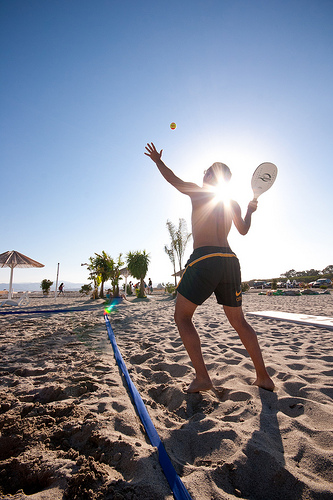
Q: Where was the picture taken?
A: It was taken at the beach.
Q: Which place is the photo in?
A: It is at the beach.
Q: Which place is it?
A: It is a beach.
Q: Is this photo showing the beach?
A: Yes, it is showing the beach.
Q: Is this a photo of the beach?
A: Yes, it is showing the beach.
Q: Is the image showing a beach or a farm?
A: It is showing a beach.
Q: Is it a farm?
A: No, it is a beach.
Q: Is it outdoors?
A: Yes, it is outdoors.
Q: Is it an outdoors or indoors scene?
A: It is outdoors.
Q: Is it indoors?
A: No, it is outdoors.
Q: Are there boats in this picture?
A: No, there are no boats.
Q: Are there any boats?
A: No, there are no boats.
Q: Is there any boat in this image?
A: No, there are no boats.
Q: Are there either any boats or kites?
A: No, there are no boats or kites.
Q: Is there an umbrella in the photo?
A: Yes, there is an umbrella.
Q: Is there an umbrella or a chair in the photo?
A: Yes, there is an umbrella.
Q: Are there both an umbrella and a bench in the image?
A: No, there is an umbrella but no benches.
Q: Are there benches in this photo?
A: No, there are no benches.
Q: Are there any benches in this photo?
A: No, there are no benches.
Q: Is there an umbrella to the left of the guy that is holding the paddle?
A: Yes, there is an umbrella to the left of the guy.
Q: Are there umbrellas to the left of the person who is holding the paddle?
A: Yes, there is an umbrella to the left of the guy.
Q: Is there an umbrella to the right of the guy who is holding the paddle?
A: No, the umbrella is to the left of the guy.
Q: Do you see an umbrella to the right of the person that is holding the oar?
A: No, the umbrella is to the left of the guy.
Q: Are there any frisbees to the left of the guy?
A: No, there is an umbrella to the left of the guy.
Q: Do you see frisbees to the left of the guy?
A: No, there is an umbrella to the left of the guy.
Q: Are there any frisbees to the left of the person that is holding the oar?
A: No, there is an umbrella to the left of the guy.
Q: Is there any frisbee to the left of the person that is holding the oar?
A: No, there is an umbrella to the left of the guy.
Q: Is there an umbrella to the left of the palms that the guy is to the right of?
A: Yes, there is an umbrella to the left of the palms.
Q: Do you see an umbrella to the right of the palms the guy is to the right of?
A: No, the umbrella is to the left of the palm trees.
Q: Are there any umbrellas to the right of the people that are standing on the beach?
A: Yes, there is an umbrella to the right of the people.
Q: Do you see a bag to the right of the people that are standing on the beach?
A: No, there is an umbrella to the right of the people.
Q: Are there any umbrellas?
A: Yes, there is an umbrella.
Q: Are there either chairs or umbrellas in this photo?
A: Yes, there is an umbrella.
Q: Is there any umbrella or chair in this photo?
A: Yes, there is an umbrella.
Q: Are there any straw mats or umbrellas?
A: Yes, there is a straw umbrella.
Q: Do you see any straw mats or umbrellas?
A: Yes, there is a straw umbrella.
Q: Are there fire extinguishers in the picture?
A: No, there are no fire extinguishers.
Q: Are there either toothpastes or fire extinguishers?
A: No, there are no fire extinguishers or toothpastes.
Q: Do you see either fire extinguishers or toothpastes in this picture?
A: No, there are no fire extinguishers or toothpastes.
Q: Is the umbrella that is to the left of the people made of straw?
A: Yes, the umbrella is made of straw.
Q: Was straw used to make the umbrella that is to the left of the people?
A: Yes, the umbrella is made of straw.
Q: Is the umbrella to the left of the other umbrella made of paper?
A: No, the umbrella is made of straw.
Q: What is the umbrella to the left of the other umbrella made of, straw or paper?
A: The umbrella is made of straw.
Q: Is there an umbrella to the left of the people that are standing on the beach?
A: Yes, there is an umbrella to the left of the people.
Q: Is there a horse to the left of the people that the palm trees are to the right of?
A: No, there is an umbrella to the left of the people.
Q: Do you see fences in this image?
A: No, there are no fences.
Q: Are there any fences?
A: No, there are no fences.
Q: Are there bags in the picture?
A: No, there are no bags.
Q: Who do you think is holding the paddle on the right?
A: The guy is holding the oar.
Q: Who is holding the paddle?
A: The guy is holding the oar.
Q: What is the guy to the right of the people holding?
A: The guy is holding the oar.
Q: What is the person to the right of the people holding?
A: The guy is holding the oar.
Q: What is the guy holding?
A: The guy is holding the oar.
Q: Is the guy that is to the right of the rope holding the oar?
A: Yes, the guy is holding the oar.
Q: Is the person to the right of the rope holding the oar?
A: Yes, the guy is holding the oar.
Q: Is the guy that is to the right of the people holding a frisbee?
A: No, the guy is holding the oar.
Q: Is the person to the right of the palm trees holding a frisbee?
A: No, the guy is holding the oar.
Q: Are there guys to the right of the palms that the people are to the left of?
A: Yes, there is a guy to the right of the palm trees.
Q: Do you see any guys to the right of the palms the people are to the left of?
A: Yes, there is a guy to the right of the palm trees.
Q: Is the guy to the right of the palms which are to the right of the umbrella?
A: Yes, the guy is to the right of the palm trees.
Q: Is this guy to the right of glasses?
A: No, the guy is to the right of the palm trees.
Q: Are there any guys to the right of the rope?
A: Yes, there is a guy to the right of the rope.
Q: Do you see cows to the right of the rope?
A: No, there is a guy to the right of the rope.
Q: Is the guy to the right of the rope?
A: Yes, the guy is to the right of the rope.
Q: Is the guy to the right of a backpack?
A: No, the guy is to the right of the rope.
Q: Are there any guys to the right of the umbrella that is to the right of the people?
A: Yes, there is a guy to the right of the umbrella.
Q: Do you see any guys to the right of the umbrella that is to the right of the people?
A: Yes, there is a guy to the right of the umbrella.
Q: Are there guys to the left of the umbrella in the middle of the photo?
A: No, the guy is to the right of the umbrella.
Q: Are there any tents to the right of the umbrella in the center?
A: No, there is a guy to the right of the umbrella.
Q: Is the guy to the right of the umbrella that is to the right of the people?
A: Yes, the guy is to the right of the umbrella.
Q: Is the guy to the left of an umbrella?
A: No, the guy is to the right of an umbrella.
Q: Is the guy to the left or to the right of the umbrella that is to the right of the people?
A: The guy is to the right of the umbrella.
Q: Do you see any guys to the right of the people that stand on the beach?
A: Yes, there is a guy to the right of the people.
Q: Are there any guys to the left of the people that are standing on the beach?
A: No, the guy is to the right of the people.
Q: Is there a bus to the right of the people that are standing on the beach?
A: No, there is a guy to the right of the people.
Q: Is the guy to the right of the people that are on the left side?
A: Yes, the guy is to the right of the people.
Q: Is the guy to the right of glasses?
A: No, the guy is to the right of the people.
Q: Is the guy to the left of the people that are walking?
A: No, the guy is to the right of the people.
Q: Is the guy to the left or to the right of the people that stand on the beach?
A: The guy is to the right of the people.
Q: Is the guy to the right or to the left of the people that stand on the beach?
A: The guy is to the right of the people.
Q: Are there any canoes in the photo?
A: No, there are no canoes.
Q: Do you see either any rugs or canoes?
A: No, there are no canoes or rugs.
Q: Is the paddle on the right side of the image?
A: Yes, the paddle is on the right of the image.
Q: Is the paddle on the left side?
A: No, the paddle is on the right of the image.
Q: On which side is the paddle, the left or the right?
A: The paddle is on the right of the image.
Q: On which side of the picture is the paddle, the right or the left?
A: The paddle is on the right of the image.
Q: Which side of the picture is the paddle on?
A: The paddle is on the right of the image.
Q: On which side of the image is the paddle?
A: The paddle is on the right of the image.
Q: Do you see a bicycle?
A: No, there are no bicycles.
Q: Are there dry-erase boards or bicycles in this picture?
A: No, there are no bicycles or dry-erase boards.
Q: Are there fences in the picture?
A: No, there are no fences.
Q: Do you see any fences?
A: No, there are no fences.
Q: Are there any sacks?
A: No, there are no sacks.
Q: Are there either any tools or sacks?
A: No, there are no sacks or tools.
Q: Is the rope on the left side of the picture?
A: Yes, the rope is on the left of the image.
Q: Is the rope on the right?
A: No, the rope is on the left of the image.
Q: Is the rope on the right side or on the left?
A: The rope is on the left of the image.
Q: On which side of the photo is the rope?
A: The rope is on the left of the image.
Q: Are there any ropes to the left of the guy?
A: Yes, there is a rope to the left of the guy.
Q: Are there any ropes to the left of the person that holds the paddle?
A: Yes, there is a rope to the left of the guy.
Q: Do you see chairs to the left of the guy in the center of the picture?
A: No, there is a rope to the left of the guy.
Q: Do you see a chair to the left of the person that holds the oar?
A: No, there is a rope to the left of the guy.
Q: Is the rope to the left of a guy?
A: Yes, the rope is to the left of a guy.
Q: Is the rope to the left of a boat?
A: No, the rope is to the left of a guy.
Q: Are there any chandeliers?
A: No, there are no chandeliers.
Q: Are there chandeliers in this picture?
A: No, there are no chandeliers.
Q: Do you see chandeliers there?
A: No, there are no chandeliers.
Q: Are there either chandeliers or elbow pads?
A: No, there are no chandeliers or elbow pads.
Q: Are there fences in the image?
A: No, there are no fences.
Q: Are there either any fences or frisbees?
A: No, there are no fences or frisbees.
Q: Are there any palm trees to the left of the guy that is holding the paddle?
A: Yes, there are palm trees to the left of the guy.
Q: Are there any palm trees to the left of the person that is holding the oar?
A: Yes, there are palm trees to the left of the guy.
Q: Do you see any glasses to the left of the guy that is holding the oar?
A: No, there are palm trees to the left of the guy.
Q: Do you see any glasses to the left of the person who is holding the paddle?
A: No, there are palm trees to the left of the guy.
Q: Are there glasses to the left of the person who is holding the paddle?
A: No, there are palm trees to the left of the guy.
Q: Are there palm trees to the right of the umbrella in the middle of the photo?
A: Yes, there are palm trees to the right of the umbrella.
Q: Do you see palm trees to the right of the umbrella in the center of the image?
A: Yes, there are palm trees to the right of the umbrella.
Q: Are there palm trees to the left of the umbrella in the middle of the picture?
A: No, the palm trees are to the right of the umbrella.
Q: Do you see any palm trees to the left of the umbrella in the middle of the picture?
A: No, the palm trees are to the right of the umbrella.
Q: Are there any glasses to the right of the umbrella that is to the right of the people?
A: No, there are palm trees to the right of the umbrella.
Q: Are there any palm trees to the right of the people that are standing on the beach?
A: Yes, there are palm trees to the right of the people.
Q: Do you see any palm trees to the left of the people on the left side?
A: No, the palm trees are to the right of the people.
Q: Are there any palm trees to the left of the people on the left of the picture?
A: No, the palm trees are to the right of the people.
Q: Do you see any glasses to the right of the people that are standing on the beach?
A: No, there are palm trees to the right of the people.